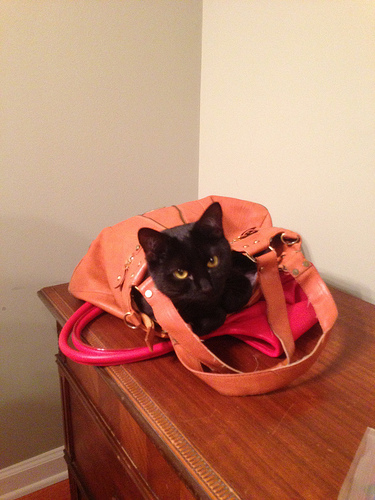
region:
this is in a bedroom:
[13, 212, 324, 407]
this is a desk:
[76, 402, 327, 496]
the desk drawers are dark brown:
[61, 392, 274, 493]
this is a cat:
[78, 240, 313, 392]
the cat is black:
[106, 225, 341, 346]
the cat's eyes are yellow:
[159, 254, 250, 276]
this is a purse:
[70, 249, 168, 325]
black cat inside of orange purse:
[129, 199, 274, 327]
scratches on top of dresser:
[225, 407, 321, 445]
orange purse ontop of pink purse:
[51, 214, 358, 400]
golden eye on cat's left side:
[204, 253, 234, 283]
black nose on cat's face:
[195, 269, 213, 299]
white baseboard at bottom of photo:
[12, 456, 83, 497]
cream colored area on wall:
[246, 82, 310, 169]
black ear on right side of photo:
[186, 201, 230, 244]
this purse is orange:
[71, 243, 163, 333]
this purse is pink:
[71, 313, 166, 388]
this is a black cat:
[161, 245, 247, 330]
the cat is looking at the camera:
[134, 237, 258, 346]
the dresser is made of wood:
[138, 397, 348, 491]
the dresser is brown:
[136, 408, 306, 485]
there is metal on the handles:
[245, 236, 320, 283]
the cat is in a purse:
[49, 188, 366, 415]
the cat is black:
[123, 183, 262, 347]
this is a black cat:
[133, 204, 273, 334]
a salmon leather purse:
[42, 191, 352, 394]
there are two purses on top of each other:
[28, 171, 372, 412]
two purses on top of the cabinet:
[34, 172, 373, 398]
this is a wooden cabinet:
[28, 281, 371, 495]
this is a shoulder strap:
[138, 247, 360, 401]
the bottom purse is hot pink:
[21, 260, 372, 417]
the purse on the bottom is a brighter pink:
[26, 243, 374, 365]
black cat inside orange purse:
[66, 177, 354, 392]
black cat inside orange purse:
[63, 176, 346, 395]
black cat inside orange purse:
[61, 179, 344, 399]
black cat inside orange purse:
[71, 177, 354, 388]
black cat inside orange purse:
[59, 174, 346, 416]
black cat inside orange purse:
[64, 184, 349, 402]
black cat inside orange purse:
[66, 171, 341, 400]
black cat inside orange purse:
[59, 181, 355, 399]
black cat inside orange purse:
[59, 184, 349, 398]